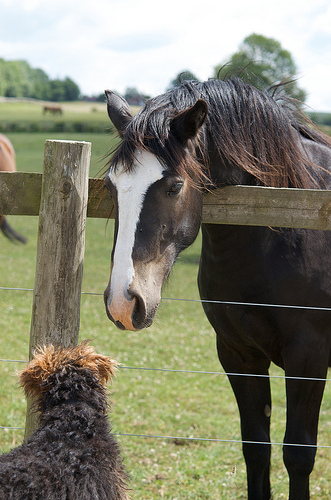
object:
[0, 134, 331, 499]
grass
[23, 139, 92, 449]
pole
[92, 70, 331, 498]
horse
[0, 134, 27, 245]
horse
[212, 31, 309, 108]
leaves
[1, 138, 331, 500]
fence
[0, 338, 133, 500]
wire hair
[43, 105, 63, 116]
horse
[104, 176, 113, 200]
eye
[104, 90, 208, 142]
ears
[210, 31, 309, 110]
tre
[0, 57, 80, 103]
trees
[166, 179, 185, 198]
eye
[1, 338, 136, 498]
dog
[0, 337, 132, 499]
shaggy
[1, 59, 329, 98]
distance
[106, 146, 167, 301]
stripe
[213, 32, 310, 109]
tree